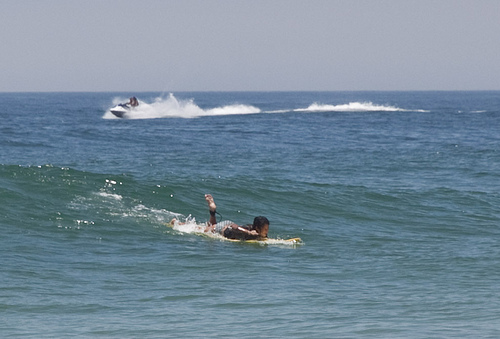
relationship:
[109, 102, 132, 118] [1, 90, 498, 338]
jet ski floating on water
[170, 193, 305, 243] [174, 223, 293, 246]
person paddling surfboard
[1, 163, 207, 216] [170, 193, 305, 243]
wave behind person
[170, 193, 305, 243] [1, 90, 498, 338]
person in middle of water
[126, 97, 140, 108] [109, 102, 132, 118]
person riding on jet ski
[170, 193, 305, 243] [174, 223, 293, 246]
person riding on surfboard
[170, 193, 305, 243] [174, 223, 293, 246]
person lying on surfboard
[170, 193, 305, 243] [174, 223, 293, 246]
person laying on surfboard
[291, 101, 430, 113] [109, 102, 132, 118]
wave behind jet ski